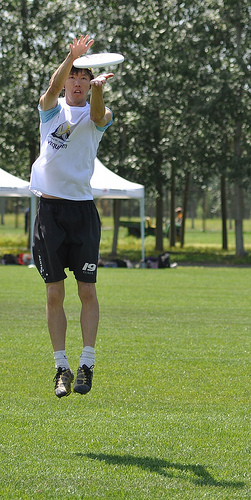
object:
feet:
[72, 361, 94, 394]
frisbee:
[72, 51, 126, 71]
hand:
[86, 71, 115, 91]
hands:
[67, 32, 96, 60]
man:
[29, 32, 113, 399]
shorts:
[30, 193, 100, 285]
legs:
[76, 229, 98, 357]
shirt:
[28, 98, 113, 205]